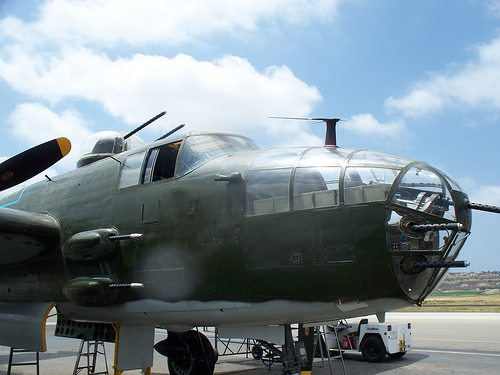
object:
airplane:
[3, 109, 495, 375]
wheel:
[166, 330, 215, 375]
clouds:
[386, 37, 499, 124]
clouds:
[0, 46, 320, 133]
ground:
[392, 147, 442, 221]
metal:
[183, 230, 224, 256]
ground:
[1, 305, 498, 374]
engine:
[60, 274, 129, 307]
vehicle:
[322, 319, 414, 363]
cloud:
[5, 0, 336, 53]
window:
[118, 140, 181, 189]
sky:
[4, 2, 499, 274]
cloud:
[346, 106, 403, 153]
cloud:
[9, 99, 95, 164]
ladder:
[71, 338, 109, 375]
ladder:
[6, 347, 39, 375]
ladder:
[314, 323, 347, 374]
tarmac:
[0, 312, 498, 374]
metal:
[413, 261, 473, 269]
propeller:
[1, 135, 71, 193]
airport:
[0, 304, 500, 373]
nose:
[397, 166, 466, 304]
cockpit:
[120, 134, 261, 195]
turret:
[75, 110, 169, 169]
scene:
[2, 0, 499, 369]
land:
[0, 281, 500, 375]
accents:
[36, 130, 135, 372]